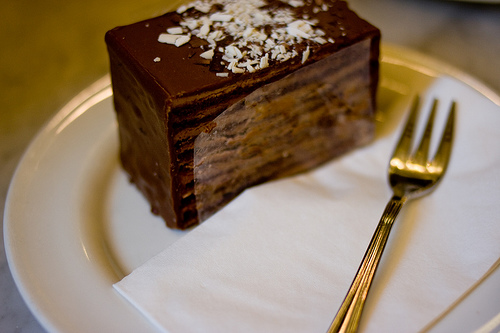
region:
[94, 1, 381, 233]
multi layer chocolate cake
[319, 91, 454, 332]
silver fork with three tines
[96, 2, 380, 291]
chocolate cake on white plate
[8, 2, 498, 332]
dessert plate with cake and fork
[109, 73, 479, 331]
fork placed on white napkin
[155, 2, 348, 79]
white sprinkles on top of cake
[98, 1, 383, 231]
chocolate cake with white topping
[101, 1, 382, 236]
one serving of chocolate cake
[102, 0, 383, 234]
square slice of cake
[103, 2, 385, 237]
chocolate layer cake with dark chocolate frosting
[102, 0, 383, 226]
Square piece of cake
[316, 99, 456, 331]
Silver fork on plate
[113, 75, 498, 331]
White napkin on plate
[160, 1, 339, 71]
White sprinkles on cake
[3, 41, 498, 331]
Round white plate with cake on top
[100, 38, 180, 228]
Chocolate coating on side of cake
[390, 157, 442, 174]
Light reflected on fork surface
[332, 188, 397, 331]
Metal handle on fork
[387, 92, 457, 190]
Three tines on fork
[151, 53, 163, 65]
Tiny white sprinkle on cake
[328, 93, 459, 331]
three-pronged silver fork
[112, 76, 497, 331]
white napkin on plate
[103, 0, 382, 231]
chocolate cake on a plate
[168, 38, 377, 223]
several layers in the cake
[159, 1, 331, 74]
coconut shavings atop the cake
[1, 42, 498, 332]
round white plate for cake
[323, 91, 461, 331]
fork is out of focus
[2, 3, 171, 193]
table under plate is blurry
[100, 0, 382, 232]
small piece of cake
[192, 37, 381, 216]
thin paper for separating cake slices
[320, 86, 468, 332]
a silver fork with three prongs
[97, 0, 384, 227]
a piece of chocolate cake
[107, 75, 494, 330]
a fork sitting on a napkin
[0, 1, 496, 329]
a plate with a piece of chocolate cake and fork on it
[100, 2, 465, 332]
a chocolate cake sitting next to a fork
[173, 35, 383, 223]
a piece of wax paper on a piece of chocolate cake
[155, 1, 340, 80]
shredded coconut on a piece of cake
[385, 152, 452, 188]
light reflecting off of a fork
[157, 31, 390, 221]
layers in a chocolate cake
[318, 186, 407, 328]
striped metal designs in a fork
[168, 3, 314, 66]
white shavings on the top of the cake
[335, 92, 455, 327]
a silver fork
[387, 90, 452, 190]
three prongs on the fork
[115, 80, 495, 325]
a clean white napkin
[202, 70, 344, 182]
layers on the cake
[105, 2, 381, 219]
a piece of chocolate cake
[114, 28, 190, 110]
chocolate frosting on the cake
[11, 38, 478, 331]
a small dessert plate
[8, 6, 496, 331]
a piece of cake on a round plate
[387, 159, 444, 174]
light reflection on the fork